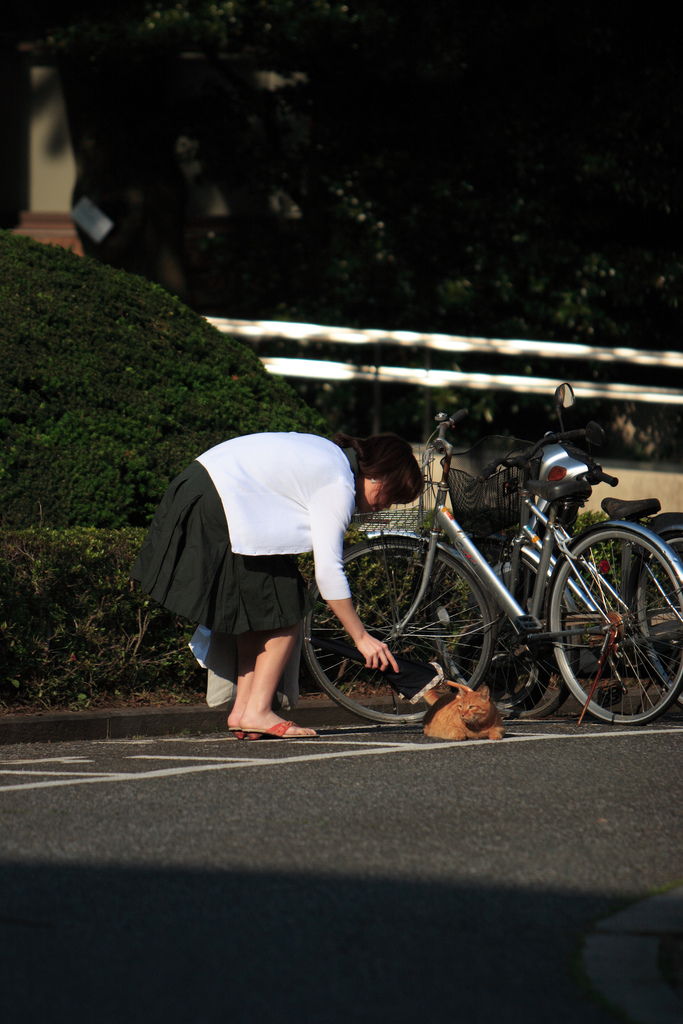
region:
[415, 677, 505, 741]
cat is laying on the ground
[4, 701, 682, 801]
white lines on the ground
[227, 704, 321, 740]
a pair of red sandals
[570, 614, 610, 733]
kickstand is down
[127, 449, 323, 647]
black flowy skirt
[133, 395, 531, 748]
woman is bending over to touch a cat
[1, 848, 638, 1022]
shadow on the ground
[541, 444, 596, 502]
silver seat on the bike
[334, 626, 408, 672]
hand of the woman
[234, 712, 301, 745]
foot of the woman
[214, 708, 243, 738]
foot of the woman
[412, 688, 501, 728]
cat on the road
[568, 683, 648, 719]
wheel on the bike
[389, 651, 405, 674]
finger on the hand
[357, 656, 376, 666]
finger on the hand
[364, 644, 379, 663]
finger on the hand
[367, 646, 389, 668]
finger on the hand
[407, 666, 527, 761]
Cat laying on road.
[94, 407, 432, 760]
Lady bending over.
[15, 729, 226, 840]
Lines on the road.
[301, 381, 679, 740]
Bicycle on the road.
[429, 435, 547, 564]
Bag on the bicycle.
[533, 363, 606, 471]
Mirror on the bicycle.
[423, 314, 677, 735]
Road behind bicycles.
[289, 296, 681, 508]
Rails along side of road.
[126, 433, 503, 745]
woman bending to touch a cat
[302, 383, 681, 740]
a red cat laying in front of a bicycle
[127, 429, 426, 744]
woman wearing white cardigan and a black skirt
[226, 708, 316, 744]
red sandals on woman's feet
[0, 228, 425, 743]
a green lush round bush behind a woman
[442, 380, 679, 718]
a bicycle with a black basket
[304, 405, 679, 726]
a bicycle with a silver basket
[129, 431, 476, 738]
woman holding a black umbrella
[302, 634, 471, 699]
an umbrella with a wooden handle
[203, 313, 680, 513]
a white metal fence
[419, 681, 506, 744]
a large orange cat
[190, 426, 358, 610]
a woman's white sweater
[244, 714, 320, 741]
a woman's red sandal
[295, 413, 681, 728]
a large gray and black bike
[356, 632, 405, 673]
the hand of a woman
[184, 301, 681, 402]
a long white fence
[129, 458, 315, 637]
a woman's black skirt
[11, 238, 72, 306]
a lush green plant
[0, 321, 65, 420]
a lush green plant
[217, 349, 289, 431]
a lush green plant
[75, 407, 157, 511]
a lush green plant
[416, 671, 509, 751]
tan cat laying in street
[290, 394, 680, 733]
bicycle parked on side of street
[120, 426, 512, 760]
woman bending down torwards cat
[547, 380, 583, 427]
rear view mirror on bicycle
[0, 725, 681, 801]
white lines drawn on street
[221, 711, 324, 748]
pair of orange heelless sandals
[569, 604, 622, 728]
brown metal kickstand on side of bicycle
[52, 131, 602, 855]
this is a city street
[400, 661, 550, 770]
the cat is sitting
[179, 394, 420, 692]
the woman is bending over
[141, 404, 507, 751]
the woman is petting the cat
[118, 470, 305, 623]
the skirt is black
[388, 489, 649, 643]
the bike is silver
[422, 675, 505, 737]
orange cat on ground